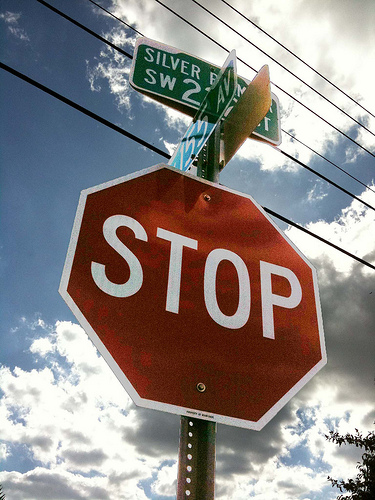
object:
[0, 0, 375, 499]
cloud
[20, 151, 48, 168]
no pole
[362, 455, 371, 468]
leaves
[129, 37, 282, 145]
green signs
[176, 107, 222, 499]
pole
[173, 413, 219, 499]
metal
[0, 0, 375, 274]
lines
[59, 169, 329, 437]
signs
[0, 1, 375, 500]
sky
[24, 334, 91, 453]
sunlight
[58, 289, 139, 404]
edge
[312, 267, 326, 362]
edge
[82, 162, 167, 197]
edge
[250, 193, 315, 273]
edge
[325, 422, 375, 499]
tree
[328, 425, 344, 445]
leaf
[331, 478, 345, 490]
leaf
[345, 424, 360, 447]
leaf